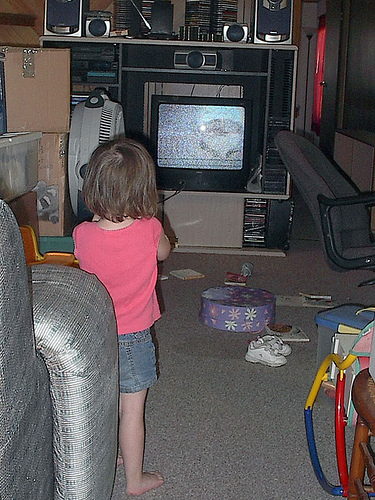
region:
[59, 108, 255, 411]
small girl standing in front of television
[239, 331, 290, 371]
girl's white tennis shoes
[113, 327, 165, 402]
girl is wearing blue jean shorts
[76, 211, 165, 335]
girl wearing pink top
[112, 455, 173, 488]
small girl has no shoes on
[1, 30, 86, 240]
cardboard boxes on the left of the tv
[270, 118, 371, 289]
back of a desk chair is grey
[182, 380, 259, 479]
carpeting is gray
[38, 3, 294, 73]
speakers are above the tv on a shelf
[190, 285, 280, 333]
round purple box with flowers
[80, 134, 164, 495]
Little girl with pink shirt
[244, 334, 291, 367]
A pair of shoes on the floor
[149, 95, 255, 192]
TV with blur signal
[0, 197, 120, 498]
Silver couch in the living room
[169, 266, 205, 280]
Book on the floor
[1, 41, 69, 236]
Paper boxes in the living room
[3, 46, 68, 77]
Tape on the paper box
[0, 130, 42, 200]
Plastic box on the table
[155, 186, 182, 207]
black cable connected to the TV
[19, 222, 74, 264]
Little orange chair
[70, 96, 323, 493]
the girl is watching TV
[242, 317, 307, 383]
shoes on the floor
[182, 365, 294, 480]
the floor is carpeted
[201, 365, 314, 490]
the carpet is gray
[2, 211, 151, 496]
the couch is silver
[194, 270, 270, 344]
the box is purple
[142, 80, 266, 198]
the tv is on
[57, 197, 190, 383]
the shirt is pink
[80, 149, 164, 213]
the hair is brown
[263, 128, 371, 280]
the chair is gray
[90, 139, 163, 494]
dark hair little girl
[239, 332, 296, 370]
a pair of white sneakers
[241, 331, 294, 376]
a pair of white shoes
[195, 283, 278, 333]
round purple box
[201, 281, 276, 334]
round box with a floral print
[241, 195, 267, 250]
bunch of DVD's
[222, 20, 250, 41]
silver and black speaker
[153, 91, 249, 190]
black television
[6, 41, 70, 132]
brown box with brown tape on it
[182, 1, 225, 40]
large collection of dvds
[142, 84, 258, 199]
TV in black plastic casing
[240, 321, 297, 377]
little girls white tennis shoes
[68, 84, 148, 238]
area fan in white plastic casing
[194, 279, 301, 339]
purple hat box with pink and white flowers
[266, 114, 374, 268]
back of black and gray office chair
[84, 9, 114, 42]
silver and black stereo speakers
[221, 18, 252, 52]
silver and black stereo speakers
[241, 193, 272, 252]
CDs stacked under TV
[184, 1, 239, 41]
stacks of CDs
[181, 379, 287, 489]
gray speckled carpet